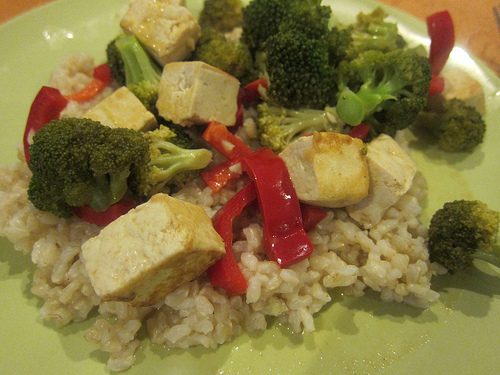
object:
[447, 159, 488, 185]
ground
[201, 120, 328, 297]
peppers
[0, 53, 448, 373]
rice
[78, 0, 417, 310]
chicken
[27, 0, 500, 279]
broccoli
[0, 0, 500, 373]
food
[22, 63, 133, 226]
tomato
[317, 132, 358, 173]
ground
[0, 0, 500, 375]
plate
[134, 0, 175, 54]
sauce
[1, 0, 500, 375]
table